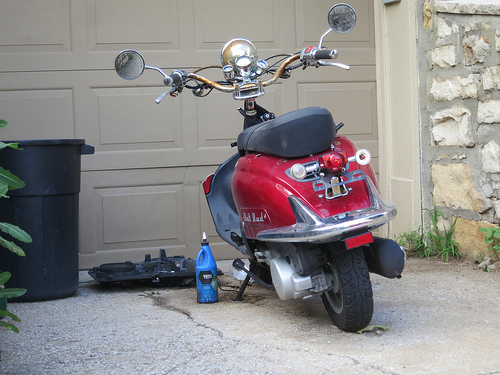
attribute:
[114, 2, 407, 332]
motorcycle — red, black, being worked on, parked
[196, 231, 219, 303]
bottle — blue, bright blue, lubricant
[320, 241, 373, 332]
tire — black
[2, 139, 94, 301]
trash can — black, tall, dark colored, plastic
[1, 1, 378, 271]
garage door — brown, tan, rectangular, light gray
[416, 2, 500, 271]
wall — stone, brick, concrete, tan, white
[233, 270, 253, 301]
kickstand — black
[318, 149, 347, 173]
taillight — red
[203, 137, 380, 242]
body — red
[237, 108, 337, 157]
seat — black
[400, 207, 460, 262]
grass — green